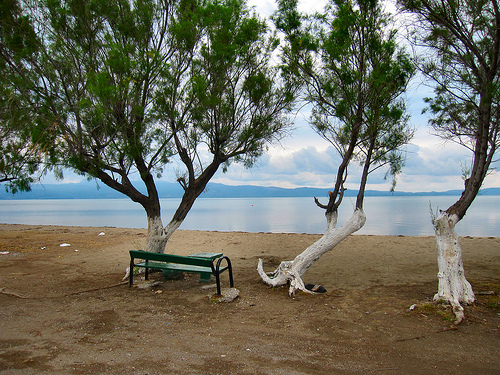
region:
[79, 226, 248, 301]
an empty park bench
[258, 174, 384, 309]
a tree that is grown slanted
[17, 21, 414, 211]
leaves on the various trees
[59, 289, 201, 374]
dirt and sand making up the beach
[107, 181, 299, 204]
rolling mountains in the background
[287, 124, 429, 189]
cloudy skies above the water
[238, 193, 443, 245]
smooth water lighting the beach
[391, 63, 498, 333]
a curvy tree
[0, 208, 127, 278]
trash and debris on the beach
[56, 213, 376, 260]
the line where the beach meets the water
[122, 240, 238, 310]
Green park bench sitting on the edge of the lake shore.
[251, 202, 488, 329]
White protective paint on tree trunks to prevent insect infestations.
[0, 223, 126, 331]
Gravel beaches along the lake shore.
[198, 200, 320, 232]
Large lake with calm waters.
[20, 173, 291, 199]
Mountainous area on the opposite shoreline.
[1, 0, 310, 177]
Green foliage covering the trees.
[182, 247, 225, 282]
Small green metal table sits in front of the bench.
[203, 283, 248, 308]
Concrete footers hold the metal bench in place.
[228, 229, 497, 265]
Brown rocky shore line suggests no waves.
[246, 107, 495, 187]
An overcast day with what might be storm clouds.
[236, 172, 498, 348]
White on the bottom half of tree trunks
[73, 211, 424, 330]
Empty park bench by the trees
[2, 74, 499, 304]
Park bench by the waterside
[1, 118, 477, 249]
Mountains in the distance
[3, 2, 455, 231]
Greenery of the tree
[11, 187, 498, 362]
Dirt beach by the lakeside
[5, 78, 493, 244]
Lots of clouds in the sky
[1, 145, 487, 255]
Nobody in or on the water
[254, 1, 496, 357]
Trees swooping to the right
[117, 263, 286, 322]
Bench coming out of the ground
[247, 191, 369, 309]
white bottom of crooked tree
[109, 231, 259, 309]
green bench behind tree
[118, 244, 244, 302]
small metal green bench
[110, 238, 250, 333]
metal green bench on sandy soil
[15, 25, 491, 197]
green trees against cloudy sky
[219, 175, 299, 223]
body of water with mountain in the background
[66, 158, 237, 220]
crooked dark branches with body of water in the background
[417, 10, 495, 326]
crooked tree with white base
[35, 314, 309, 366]
light brown sandy soil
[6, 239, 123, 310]
root protruding from light brown sandy soil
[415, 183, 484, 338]
the tree painted in white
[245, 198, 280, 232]
the water in the river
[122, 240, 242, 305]
the green color table to sit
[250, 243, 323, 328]
the roots of the tree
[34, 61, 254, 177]
the trees on the river side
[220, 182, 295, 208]
the mountains on the river side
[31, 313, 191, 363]
the sand on the river side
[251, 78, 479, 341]
two trees painted with white color side by side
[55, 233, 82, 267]
the waste paper on the river side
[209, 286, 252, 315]
the concrete mix to the table